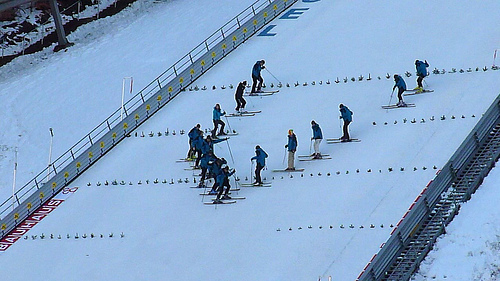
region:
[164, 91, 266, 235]
the people are visible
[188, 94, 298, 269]
the people are visible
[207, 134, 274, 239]
the people are visible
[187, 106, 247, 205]
the people are visible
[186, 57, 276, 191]
these are people in the photo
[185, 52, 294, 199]
they are snow skating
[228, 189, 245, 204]
he is wearing skiis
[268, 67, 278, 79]
this is a stick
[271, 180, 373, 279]
the path is slanting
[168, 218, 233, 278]
the path is white in color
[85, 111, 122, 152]
this is a boundary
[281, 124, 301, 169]
the man is standing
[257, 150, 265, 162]
the jacket is blue in color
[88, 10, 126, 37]
snow is on the path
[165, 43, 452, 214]
group of people on skis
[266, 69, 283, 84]
long and skinny ski pole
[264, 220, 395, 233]
row of little black objects sticking out of the snow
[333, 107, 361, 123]
light blue Winter jacket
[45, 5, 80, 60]
tree trunk sticking out of the snow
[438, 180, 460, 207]
snow on the metal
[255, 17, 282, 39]
large blue letter L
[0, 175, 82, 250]
red and white banner on the ground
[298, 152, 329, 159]
long and thin skis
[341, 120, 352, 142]
black pants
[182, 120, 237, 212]
a row of people skiing down a hill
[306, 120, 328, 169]
a person wearing skis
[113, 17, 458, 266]
a ski sloped covered in snow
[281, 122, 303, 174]
a person wearing white pants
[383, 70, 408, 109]
a person holding a ski pole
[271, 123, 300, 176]
a person wearing a yellow hat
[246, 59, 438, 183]
seven people skiing down a hill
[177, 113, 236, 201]
several people wearing blue jackets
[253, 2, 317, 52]
blue letters on a ski slope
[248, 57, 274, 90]
a person leaned over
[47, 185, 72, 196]
the signs are yellow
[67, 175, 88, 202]
the signs are yellow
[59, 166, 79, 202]
the signs are yellow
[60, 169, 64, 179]
the signs are yellow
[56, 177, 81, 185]
the signs are yellow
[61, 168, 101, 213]
the signs are yellow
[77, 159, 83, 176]
the signs are yellow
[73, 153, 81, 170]
the signs are yellow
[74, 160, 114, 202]
the signs are yellow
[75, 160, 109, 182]
the signs are yellow